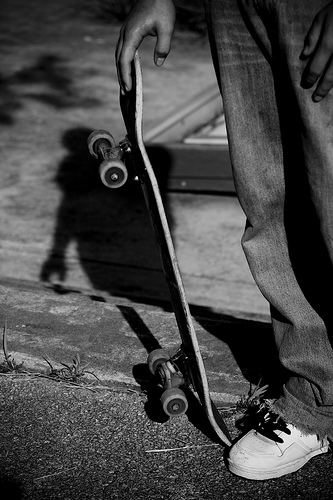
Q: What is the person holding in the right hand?
A: A skateboard.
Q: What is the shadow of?
A: The person holding a skateboard.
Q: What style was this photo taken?
A: Black and white.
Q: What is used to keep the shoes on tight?
A: Shoe laces.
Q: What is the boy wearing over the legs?
A: Blue jeans.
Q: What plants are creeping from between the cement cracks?
A: Grass.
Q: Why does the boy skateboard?
A: Because it is fun.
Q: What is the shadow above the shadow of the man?
A: Tree branch and leaves.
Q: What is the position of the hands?
A: Open.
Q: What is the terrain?
A: Flat and concrete floor.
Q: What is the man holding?
A: A skateboard.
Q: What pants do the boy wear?
A: Jeans.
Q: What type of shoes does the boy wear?
A: Sneakers.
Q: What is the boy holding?
A: A skateboard.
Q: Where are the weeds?
A: In the cracks on the sidewalk.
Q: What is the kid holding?
A: A skateboard.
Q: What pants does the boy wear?
A: Jeans.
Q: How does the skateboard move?
A: With the wheels.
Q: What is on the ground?
A: The shadow of the man.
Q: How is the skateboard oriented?
A: Vertically.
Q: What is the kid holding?
A: Skateboard.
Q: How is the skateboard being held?
A: Sideways.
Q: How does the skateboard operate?
A: On wheels.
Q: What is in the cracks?
A: Weeds.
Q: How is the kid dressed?
A: In jeans.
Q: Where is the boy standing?
A: In the street.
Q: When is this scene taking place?
A: Daytime.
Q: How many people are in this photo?
A: One.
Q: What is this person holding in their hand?
A: Skateboard.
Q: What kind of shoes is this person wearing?
A: Sneakers.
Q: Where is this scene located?
A: On the street.